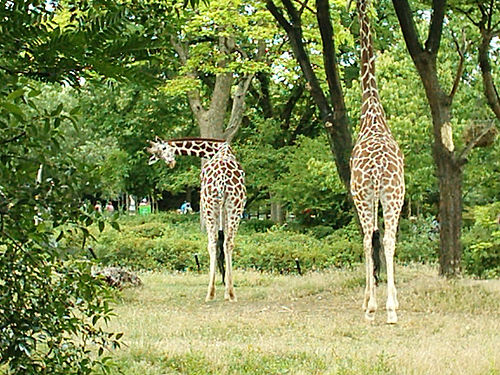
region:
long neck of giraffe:
[184, 123, 220, 163]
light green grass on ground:
[273, 284, 326, 350]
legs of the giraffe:
[186, 220, 251, 293]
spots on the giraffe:
[361, 147, 411, 185]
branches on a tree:
[266, 19, 343, 95]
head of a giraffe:
[141, 138, 174, 183]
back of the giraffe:
[331, 131, 403, 215]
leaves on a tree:
[6, 157, 93, 284]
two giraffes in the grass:
[151, 29, 418, 264]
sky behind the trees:
[276, 46, 301, 81]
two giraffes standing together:
[119, 2, 499, 348]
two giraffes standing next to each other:
[50, 10, 437, 336]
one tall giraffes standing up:
[308, 9, 449, 324]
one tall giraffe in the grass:
[329, 4, 441, 366]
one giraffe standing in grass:
[331, 5, 448, 353]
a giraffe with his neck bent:
[135, 100, 285, 313]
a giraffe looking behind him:
[129, 102, 268, 316]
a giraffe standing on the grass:
[99, 82, 286, 347]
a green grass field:
[130, 272, 315, 373]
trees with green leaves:
[142, 0, 492, 194]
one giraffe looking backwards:
[125, 110, 275, 317]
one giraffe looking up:
[291, 0, 430, 325]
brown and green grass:
[78, 262, 493, 372]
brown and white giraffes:
[135, 2, 424, 327]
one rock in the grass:
[82, 255, 152, 295]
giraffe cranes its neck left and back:
[141, 112, 271, 307]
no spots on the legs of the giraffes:
[193, 235, 426, 335]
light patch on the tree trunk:
[417, 105, 472, 179]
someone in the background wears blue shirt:
[169, 192, 205, 228]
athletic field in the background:
[111, 183, 186, 220]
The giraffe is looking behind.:
[132, 120, 267, 317]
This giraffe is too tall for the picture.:
[337, 0, 422, 334]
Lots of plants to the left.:
[2, 2, 111, 362]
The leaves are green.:
[37, 29, 176, 127]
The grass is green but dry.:
[158, 315, 350, 374]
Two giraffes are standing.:
[142, 1, 421, 336]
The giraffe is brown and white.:
[113, 117, 258, 308]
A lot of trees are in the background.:
[254, 26, 341, 238]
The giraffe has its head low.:
[129, 122, 266, 315]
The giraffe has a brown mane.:
[153, 126, 238, 148]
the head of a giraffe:
[143, 132, 185, 179]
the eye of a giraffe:
[159, 139, 169, 152]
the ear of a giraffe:
[146, 151, 159, 166]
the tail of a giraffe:
[211, 187, 229, 287]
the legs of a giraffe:
[353, 203, 407, 331]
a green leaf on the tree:
[105, 215, 123, 234]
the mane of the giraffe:
[165, 133, 230, 145]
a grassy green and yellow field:
[11, 260, 498, 372]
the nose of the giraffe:
[162, 152, 180, 169]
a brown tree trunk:
[431, 160, 473, 282]